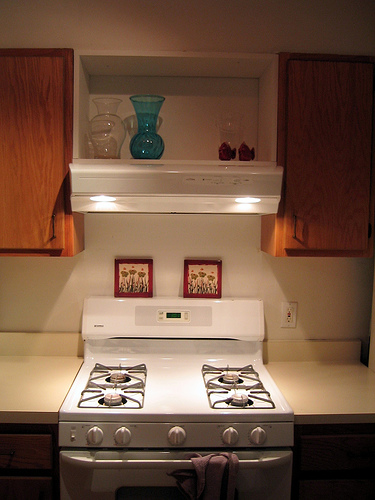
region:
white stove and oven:
[53, 290, 295, 497]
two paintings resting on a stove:
[109, 253, 231, 302]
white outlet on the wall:
[278, 296, 300, 332]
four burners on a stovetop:
[76, 358, 276, 412]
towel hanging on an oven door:
[173, 445, 243, 498]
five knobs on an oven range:
[81, 423, 271, 448]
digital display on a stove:
[155, 306, 194, 323]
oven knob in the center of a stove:
[165, 422, 188, 448]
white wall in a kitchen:
[0, 207, 372, 349]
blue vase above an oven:
[126, 86, 177, 162]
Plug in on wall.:
[272, 294, 302, 334]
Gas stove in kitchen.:
[89, 354, 155, 425]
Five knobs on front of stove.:
[80, 421, 282, 448]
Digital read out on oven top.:
[150, 304, 199, 324]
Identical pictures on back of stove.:
[103, 244, 228, 306]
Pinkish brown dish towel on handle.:
[173, 429, 274, 493]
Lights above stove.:
[90, 189, 267, 222]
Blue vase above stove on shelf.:
[129, 78, 167, 168]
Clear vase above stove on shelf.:
[90, 90, 130, 166]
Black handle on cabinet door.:
[40, 194, 70, 253]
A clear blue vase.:
[126, 88, 167, 161]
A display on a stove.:
[154, 309, 192, 323]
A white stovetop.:
[78, 349, 275, 410]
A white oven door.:
[62, 446, 293, 496]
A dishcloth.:
[172, 454, 242, 499]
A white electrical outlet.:
[278, 300, 298, 326]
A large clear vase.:
[86, 95, 126, 157]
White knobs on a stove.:
[83, 426, 266, 447]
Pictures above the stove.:
[112, 258, 220, 297]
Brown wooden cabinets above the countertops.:
[3, 51, 374, 257]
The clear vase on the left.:
[91, 81, 131, 161]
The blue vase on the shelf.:
[126, 91, 169, 159]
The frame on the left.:
[112, 258, 156, 297]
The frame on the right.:
[184, 258, 224, 295]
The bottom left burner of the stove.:
[84, 385, 142, 409]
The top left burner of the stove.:
[91, 356, 145, 387]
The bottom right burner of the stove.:
[206, 384, 269, 411]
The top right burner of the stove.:
[199, 362, 262, 387]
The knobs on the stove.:
[79, 420, 273, 452]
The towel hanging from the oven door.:
[175, 451, 248, 499]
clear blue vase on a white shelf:
[128, 91, 167, 157]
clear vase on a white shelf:
[88, 95, 128, 157]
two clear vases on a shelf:
[85, 89, 164, 161]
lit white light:
[231, 196, 261, 204]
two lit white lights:
[86, 192, 261, 208]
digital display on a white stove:
[152, 308, 192, 321]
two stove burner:
[195, 362, 275, 409]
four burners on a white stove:
[76, 360, 279, 410]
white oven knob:
[163, 424, 189, 447]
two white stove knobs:
[218, 426, 270, 446]